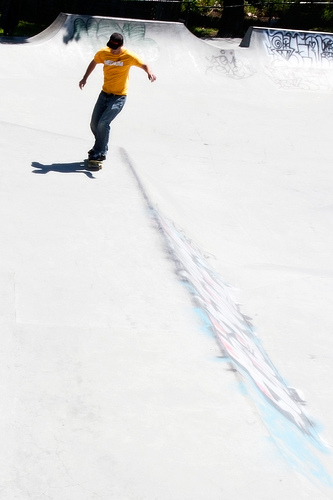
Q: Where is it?
A: This is at the skate park.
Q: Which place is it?
A: It is a skate park.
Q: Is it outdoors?
A: Yes, it is outdoors.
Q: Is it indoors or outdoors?
A: It is outdoors.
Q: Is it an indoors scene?
A: No, it is outdoors.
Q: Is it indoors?
A: No, it is outdoors.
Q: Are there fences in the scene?
A: No, there are no fences.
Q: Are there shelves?
A: No, there are no shelves.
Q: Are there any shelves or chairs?
A: No, there are no shelves or chairs.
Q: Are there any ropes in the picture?
A: No, there are no ropes.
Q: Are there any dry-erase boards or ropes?
A: No, there are no ropes or dry-erase boards.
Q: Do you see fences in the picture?
A: No, there are no fences.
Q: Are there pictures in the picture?
A: No, there are no pictures.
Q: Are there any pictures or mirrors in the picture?
A: No, there are no pictures or mirrors.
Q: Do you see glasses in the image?
A: No, there are no glasses.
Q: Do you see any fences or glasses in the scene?
A: No, there are no glasses or fences.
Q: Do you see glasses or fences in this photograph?
A: No, there are no glasses or fences.